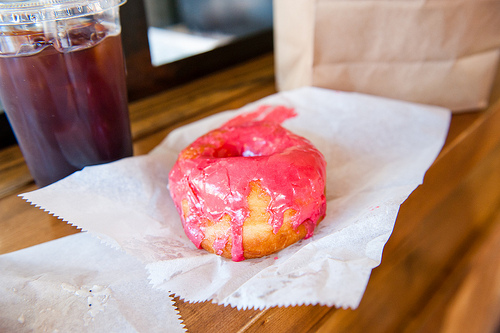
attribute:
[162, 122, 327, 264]
donut — pink, glazed, brown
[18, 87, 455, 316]
paper — white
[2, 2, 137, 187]
cup — clear, plastic, small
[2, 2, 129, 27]
top — plastic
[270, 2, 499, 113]
bag — lunch, brown, paper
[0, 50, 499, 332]
table — wood, wooden, brown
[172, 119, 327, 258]
icing — pink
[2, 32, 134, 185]
liquid — brown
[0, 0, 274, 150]
window — black framed